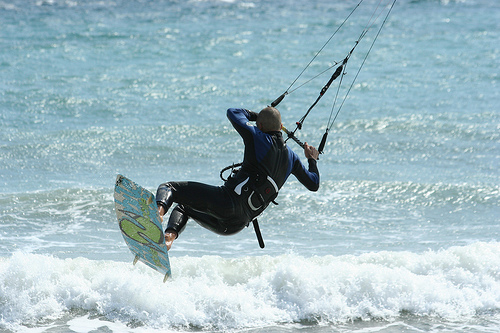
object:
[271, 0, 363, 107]
chords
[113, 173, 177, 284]
board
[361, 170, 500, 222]
water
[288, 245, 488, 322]
wave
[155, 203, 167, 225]
feet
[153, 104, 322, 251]
man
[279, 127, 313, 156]
handle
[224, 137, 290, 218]
harness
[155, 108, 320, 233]
wetsuit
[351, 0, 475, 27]
kite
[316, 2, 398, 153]
string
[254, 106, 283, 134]
head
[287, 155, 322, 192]
arm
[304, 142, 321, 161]
hand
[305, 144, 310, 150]
thumb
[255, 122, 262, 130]
ear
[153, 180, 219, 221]
leg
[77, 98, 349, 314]
mid air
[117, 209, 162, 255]
designs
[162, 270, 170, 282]
fins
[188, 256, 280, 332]
waves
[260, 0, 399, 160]
parasail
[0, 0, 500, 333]
ocean